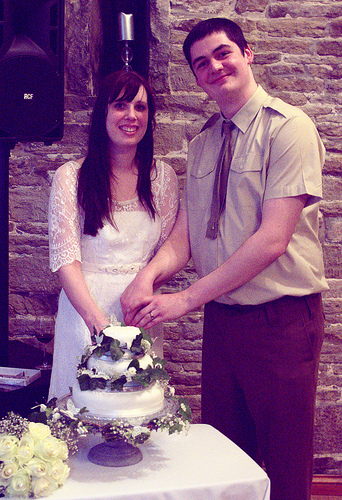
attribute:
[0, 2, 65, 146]
speaker — black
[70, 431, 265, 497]
tablecloth — white 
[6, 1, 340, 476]
wall — stone